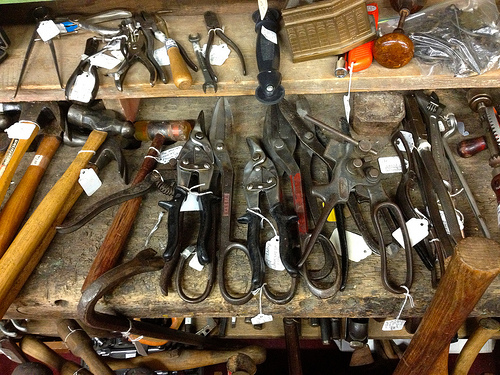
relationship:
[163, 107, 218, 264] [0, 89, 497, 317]
tool laying on a board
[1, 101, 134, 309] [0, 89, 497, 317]
tools laying on a board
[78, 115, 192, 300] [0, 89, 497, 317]
tools laying on a board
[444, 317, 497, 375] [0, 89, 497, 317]
tools laying on a board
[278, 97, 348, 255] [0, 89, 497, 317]
tools laying on a board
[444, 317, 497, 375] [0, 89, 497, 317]
tools layong on a board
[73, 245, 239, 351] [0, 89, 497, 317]
crowbar on edge of board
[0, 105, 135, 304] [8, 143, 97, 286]
hammer with handle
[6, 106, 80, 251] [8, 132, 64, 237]
hammer with handle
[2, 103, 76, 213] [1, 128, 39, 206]
hammer with handle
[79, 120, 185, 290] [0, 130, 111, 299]
mallet with a handle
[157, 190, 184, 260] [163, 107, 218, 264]
handle of tool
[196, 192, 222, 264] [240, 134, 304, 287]
handle of tool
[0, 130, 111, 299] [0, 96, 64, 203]
handle of hammers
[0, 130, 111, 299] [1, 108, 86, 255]
handle of hammers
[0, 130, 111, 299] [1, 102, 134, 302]
handle of hammers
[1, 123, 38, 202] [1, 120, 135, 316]
handle of hammers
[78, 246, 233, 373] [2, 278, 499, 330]
pry bar hanging off shelf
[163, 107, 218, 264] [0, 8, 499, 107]
tool on shelf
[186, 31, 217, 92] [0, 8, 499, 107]
tool on shelf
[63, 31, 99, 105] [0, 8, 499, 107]
tool on shelf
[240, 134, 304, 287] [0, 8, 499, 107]
tool on shelf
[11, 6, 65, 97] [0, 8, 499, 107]
tool on shelf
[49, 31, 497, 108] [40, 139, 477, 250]
shelf full of tools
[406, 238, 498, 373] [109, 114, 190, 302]
handle of hammer